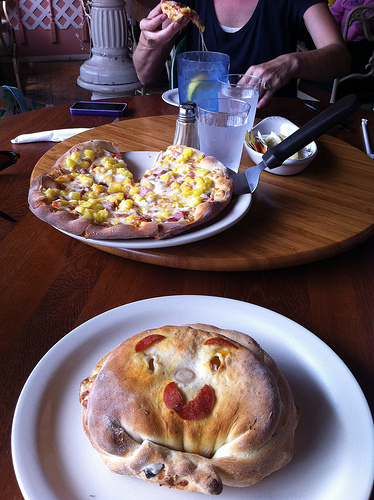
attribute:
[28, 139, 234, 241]
pizza — personal size, cooked, baked, small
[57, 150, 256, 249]
plate — white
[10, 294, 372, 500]
plate — white, round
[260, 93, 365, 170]
handle — black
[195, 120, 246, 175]
water — cold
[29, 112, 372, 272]
platter — round, brown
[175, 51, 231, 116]
glass — blue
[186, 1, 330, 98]
shirt — black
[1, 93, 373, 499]
table — wooden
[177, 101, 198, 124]
shaker top — silver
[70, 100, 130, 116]
cellphone — blue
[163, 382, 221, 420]
pepperoni — broken, red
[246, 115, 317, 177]
bowl — white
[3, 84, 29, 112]
strap — blue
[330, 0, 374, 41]
sweater — violet